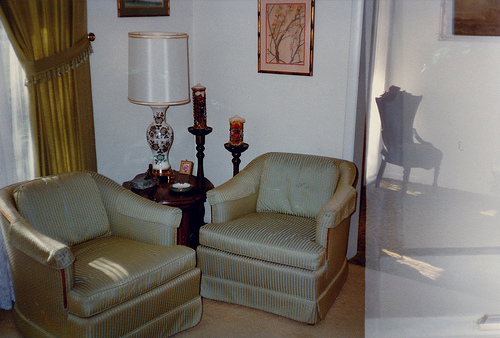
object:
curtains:
[1, 0, 100, 179]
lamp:
[128, 30, 191, 176]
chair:
[0, 170, 204, 337]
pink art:
[256, 2, 316, 77]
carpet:
[0, 261, 374, 338]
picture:
[123, 0, 169, 14]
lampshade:
[128, 32, 190, 107]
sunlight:
[86, 256, 127, 281]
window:
[0, 0, 72, 188]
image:
[452, 1, 500, 37]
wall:
[380, 0, 497, 201]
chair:
[375, 84, 444, 197]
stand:
[223, 141, 248, 177]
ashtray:
[169, 182, 194, 194]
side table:
[122, 169, 215, 249]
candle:
[224, 115, 249, 177]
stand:
[188, 126, 213, 177]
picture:
[264, 3, 305, 66]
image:
[260, 2, 310, 75]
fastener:
[85, 32, 96, 42]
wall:
[83, 1, 356, 261]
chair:
[195, 151, 359, 326]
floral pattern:
[146, 105, 175, 170]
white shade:
[127, 33, 188, 105]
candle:
[187, 82, 213, 193]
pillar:
[189, 125, 212, 195]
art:
[114, 0, 171, 18]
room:
[0, 0, 498, 335]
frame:
[256, 0, 315, 77]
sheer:
[0, 24, 38, 310]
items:
[130, 159, 195, 194]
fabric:
[255, 152, 339, 219]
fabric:
[12, 170, 109, 245]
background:
[369, 0, 499, 337]